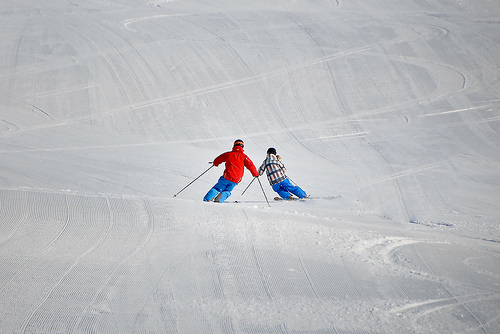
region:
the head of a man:
[216, 132, 261, 169]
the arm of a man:
[196, 142, 239, 177]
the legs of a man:
[204, 176, 244, 221]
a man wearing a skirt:
[210, 119, 261, 191]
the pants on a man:
[199, 163, 251, 205]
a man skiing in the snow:
[185, 120, 279, 234]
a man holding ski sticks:
[179, 128, 284, 205]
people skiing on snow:
[120, 108, 317, 229]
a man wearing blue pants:
[183, 168, 248, 210]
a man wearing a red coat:
[202, 110, 268, 191]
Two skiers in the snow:
[173, 126, 318, 226]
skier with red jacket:
[209, 136, 261, 190]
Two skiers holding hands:
[168, 126, 313, 213]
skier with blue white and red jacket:
[255, 158, 306, 191]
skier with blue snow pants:
[204, 177, 250, 204]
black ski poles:
[161, 133, 279, 219]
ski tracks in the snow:
[2, 3, 490, 333]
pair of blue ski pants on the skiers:
[195, 171, 310, 208]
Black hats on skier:
[265, 138, 280, 160]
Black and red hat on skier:
[227, 136, 250, 149]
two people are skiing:
[191, 112, 327, 234]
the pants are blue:
[195, 172, 300, 207]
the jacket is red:
[210, 150, 260, 183]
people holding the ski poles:
[121, 107, 326, 242]